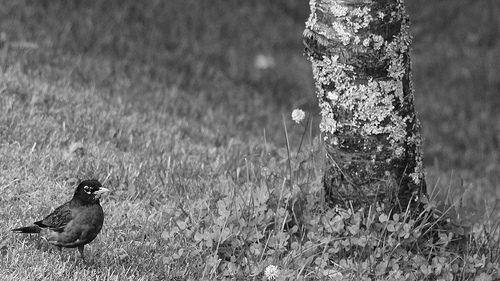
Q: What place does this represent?
A: It represents the field.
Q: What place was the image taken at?
A: It was taken at the field.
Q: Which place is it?
A: It is a field.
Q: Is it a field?
A: Yes, it is a field.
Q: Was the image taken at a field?
A: Yes, it was taken in a field.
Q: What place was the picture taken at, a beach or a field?
A: It was taken at a field.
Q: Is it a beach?
A: No, it is a field.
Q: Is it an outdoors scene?
A: Yes, it is outdoors.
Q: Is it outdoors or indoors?
A: It is outdoors.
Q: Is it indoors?
A: No, it is outdoors.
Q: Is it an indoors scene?
A: No, it is outdoors.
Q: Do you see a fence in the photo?
A: No, there are no fences.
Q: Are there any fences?
A: No, there are no fences.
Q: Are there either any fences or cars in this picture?
A: No, there are no fences or cars.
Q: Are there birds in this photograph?
A: Yes, there is a bird.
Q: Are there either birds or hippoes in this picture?
A: Yes, there is a bird.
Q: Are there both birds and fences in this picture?
A: No, there is a bird but no fences.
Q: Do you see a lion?
A: No, there are no lions.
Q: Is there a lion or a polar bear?
A: No, there are no lions or polar bears.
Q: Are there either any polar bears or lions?
A: No, there are no lions or polar bears.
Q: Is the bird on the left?
A: Yes, the bird is on the left of the image.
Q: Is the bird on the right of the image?
A: No, the bird is on the left of the image.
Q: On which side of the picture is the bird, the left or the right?
A: The bird is on the left of the image.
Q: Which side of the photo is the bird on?
A: The bird is on the left of the image.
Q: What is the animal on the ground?
A: The animal is a bird.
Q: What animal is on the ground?
A: The animal is a bird.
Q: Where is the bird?
A: The bird is on the ground.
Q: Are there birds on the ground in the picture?
A: Yes, there is a bird on the ground.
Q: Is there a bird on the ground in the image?
A: Yes, there is a bird on the ground.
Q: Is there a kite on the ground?
A: No, there is a bird on the ground.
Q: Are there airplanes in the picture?
A: No, there are no airplanes.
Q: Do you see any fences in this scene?
A: No, there are no fences.